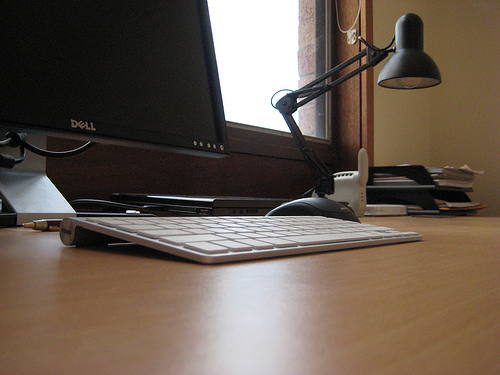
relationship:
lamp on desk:
[258, 13, 442, 223] [1, 220, 499, 374]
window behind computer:
[204, 0, 337, 148] [4, 3, 244, 216]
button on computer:
[189, 139, 199, 147] [4, 3, 244, 216]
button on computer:
[196, 137, 206, 150] [4, 3, 244, 216]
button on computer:
[204, 141, 212, 150] [4, 3, 244, 216]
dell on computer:
[67, 115, 105, 136] [4, 3, 244, 216]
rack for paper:
[363, 159, 479, 217] [420, 162, 482, 190]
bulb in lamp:
[395, 78, 422, 88] [258, 13, 442, 223]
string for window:
[328, 4, 370, 44] [204, 0, 337, 148]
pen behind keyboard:
[18, 214, 59, 235] [68, 201, 421, 257]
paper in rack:
[420, 162, 482, 190] [363, 159, 479, 217]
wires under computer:
[8, 134, 102, 165] [4, 3, 244, 216]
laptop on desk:
[119, 182, 289, 216] [1, 220, 499, 374]